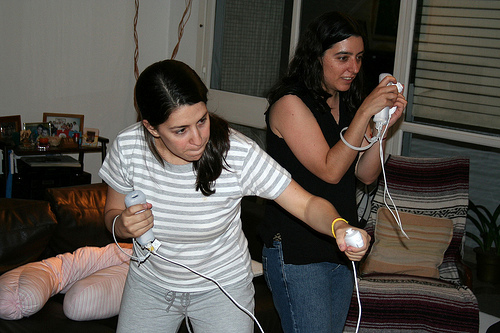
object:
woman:
[104, 27, 372, 332]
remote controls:
[111, 191, 367, 333]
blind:
[410, 3, 498, 131]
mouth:
[338, 75, 356, 84]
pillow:
[0, 239, 142, 322]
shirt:
[100, 117, 293, 291]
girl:
[268, 14, 397, 324]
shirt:
[260, 92, 366, 271]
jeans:
[261, 230, 359, 332]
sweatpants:
[118, 267, 253, 333]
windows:
[206, 0, 500, 136]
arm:
[233, 135, 371, 263]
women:
[100, 16, 410, 332]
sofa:
[1, 181, 156, 332]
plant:
[464, 199, 497, 283]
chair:
[340, 151, 478, 332]